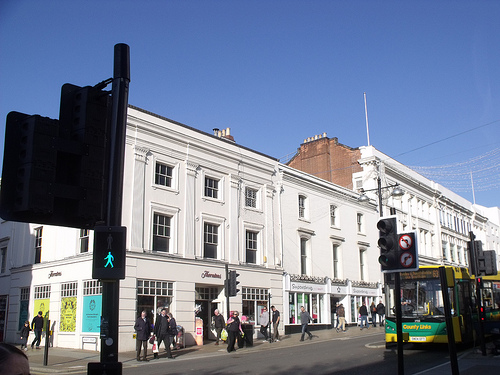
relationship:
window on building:
[201, 171, 226, 205] [125, 107, 390, 322]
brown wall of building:
[290, 140, 362, 187] [283, 132, 478, 270]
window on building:
[148, 156, 176, 188] [4, 99, 281, 353]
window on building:
[197, 216, 220, 257] [4, 99, 281, 353]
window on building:
[331, 238, 343, 280] [275, 159, 383, 330]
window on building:
[200, 215, 222, 260] [0, 102, 381, 352]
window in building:
[199, 216, 219, 261] [4, 99, 281, 353]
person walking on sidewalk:
[133, 310, 152, 360] [3, 313, 383, 373]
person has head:
[131, 307, 153, 360] [141, 307, 148, 320]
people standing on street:
[17, 298, 393, 358] [0, 317, 498, 373]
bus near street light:
[377, 263, 495, 352] [376, 207, 421, 374]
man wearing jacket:
[296, 302, 316, 342] [294, 307, 314, 324]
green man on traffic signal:
[100, 251, 112, 266] [96, 227, 123, 278]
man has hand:
[154, 302, 177, 356] [149, 331, 157, 341]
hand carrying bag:
[149, 331, 157, 341] [145, 331, 162, 353]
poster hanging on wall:
[59, 295, 78, 334] [26, 254, 104, 348]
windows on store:
[134, 277, 175, 295] [1, 254, 288, 353]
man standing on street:
[153, 302, 179, 359] [88, 321, 451, 374]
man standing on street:
[131, 300, 152, 362] [88, 321, 451, 374]